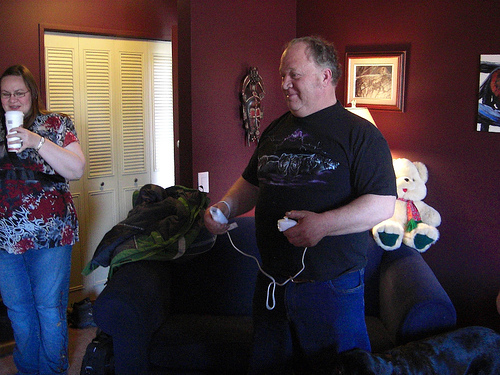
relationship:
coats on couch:
[84, 183, 218, 268] [93, 218, 280, 358]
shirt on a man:
[237, 100, 397, 281] [202, 37, 398, 373]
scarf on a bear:
[396, 196, 421, 234] [371, 155, 441, 253]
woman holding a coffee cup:
[1, 63, 87, 373] [2, 110, 24, 153]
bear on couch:
[371, 155, 441, 253] [91, 211, 456, 371]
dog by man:
[322, 320, 497, 373] [202, 37, 398, 373]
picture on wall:
[353, 64, 393, 98] [296, 4, 498, 328]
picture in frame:
[353, 64, 393, 98] [342, 47, 406, 113]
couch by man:
[102, 231, 257, 371] [202, 37, 398, 373]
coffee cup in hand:
[2, 110, 28, 147] [8, 121, 42, 150]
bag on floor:
[76, 324, 107, 373] [62, 326, 88, 372]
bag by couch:
[76, 324, 107, 373] [97, 250, 255, 366]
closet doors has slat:
[42, 31, 177, 313] [121, 160, 157, 168]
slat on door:
[86, 98, 110, 108] [82, 47, 114, 247]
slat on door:
[122, 78, 145, 88] [122, 50, 151, 213]